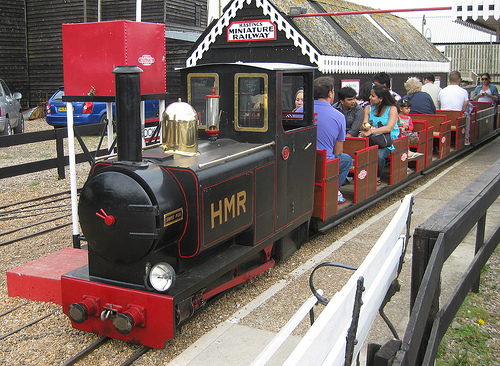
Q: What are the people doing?
A: Riding a miniature train.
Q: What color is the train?
A: Black and red.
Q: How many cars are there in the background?
A: 2.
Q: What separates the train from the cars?
A: Fence.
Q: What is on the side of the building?
A: Sign.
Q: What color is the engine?
A: Black and red.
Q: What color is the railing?
A: Black.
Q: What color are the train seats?
A: Red.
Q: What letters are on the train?
A: HMR.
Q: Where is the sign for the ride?
A: On a small building.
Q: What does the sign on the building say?
A: Miniature Railway.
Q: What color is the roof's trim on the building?
A: White.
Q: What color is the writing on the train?
A: Gold.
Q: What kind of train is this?
A: Miniature.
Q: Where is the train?
A: On the track.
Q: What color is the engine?
A: Black and red.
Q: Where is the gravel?
A: Under the track.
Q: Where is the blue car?
A: Behind the station.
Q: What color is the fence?
A: Black.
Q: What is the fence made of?
A: Wood.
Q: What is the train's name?
A: HMR.